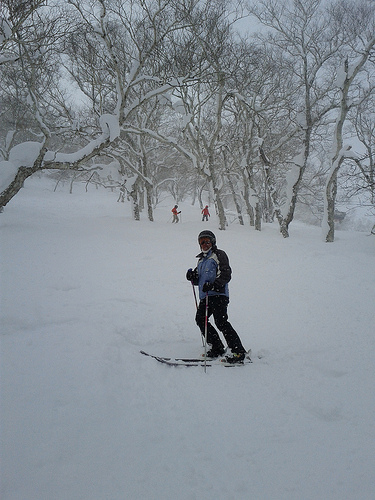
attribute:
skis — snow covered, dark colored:
[140, 346, 240, 371]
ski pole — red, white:
[204, 290, 209, 362]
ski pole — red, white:
[191, 281, 200, 309]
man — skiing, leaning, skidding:
[185, 230, 247, 362]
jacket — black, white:
[194, 247, 232, 300]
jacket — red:
[171, 206, 178, 216]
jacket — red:
[202, 208, 210, 216]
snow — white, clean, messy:
[1, 177, 374, 498]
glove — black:
[186, 266, 196, 285]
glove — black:
[210, 279, 226, 294]